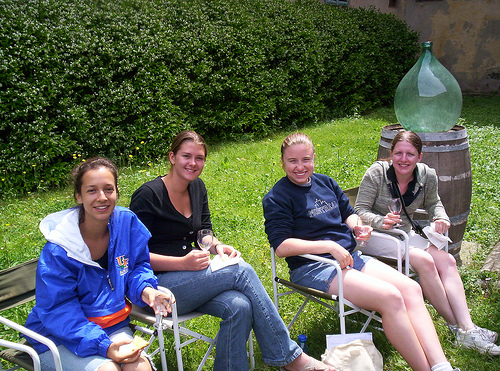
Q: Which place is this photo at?
A: It is at the yard.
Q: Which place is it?
A: It is a yard.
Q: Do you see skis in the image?
A: No, there are no skis.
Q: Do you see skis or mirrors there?
A: No, there are no skis or mirrors.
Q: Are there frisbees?
A: No, there are no frisbees.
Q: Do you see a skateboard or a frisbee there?
A: No, there are no frisbees or skateboards.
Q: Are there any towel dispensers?
A: No, there are no towel dispensers.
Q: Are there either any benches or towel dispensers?
A: No, there are no towel dispensers or benches.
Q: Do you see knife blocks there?
A: No, there are no knife blocks.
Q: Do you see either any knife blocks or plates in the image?
A: No, there are no knife blocks or plates.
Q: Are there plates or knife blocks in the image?
A: No, there are no knife blocks or plates.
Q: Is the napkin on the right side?
A: Yes, the napkin is on the right of the image.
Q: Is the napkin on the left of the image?
A: No, the napkin is on the right of the image.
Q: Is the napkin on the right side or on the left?
A: The napkin is on the right of the image.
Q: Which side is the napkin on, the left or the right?
A: The napkin is on the right of the image.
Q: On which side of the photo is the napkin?
A: The napkin is on the right of the image.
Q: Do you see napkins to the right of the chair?
A: Yes, there is a napkin to the right of the chair.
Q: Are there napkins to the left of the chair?
A: No, the napkin is to the right of the chair.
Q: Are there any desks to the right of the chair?
A: No, there is a napkin to the right of the chair.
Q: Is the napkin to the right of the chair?
A: Yes, the napkin is to the right of the chair.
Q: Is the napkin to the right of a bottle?
A: No, the napkin is to the right of the chair.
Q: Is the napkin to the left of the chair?
A: No, the napkin is to the right of the chair.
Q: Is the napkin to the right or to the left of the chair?
A: The napkin is to the right of the chair.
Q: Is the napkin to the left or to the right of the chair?
A: The napkin is to the right of the chair.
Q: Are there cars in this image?
A: No, there are no cars.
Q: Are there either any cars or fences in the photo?
A: No, there are no cars or fences.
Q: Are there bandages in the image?
A: No, there are no bandages.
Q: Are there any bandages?
A: No, there are no bandages.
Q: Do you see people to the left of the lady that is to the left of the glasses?
A: Yes, there is a person to the left of the lady.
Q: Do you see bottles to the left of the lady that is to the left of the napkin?
A: No, there is a person to the left of the lady.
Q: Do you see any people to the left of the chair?
A: Yes, there is a person to the left of the chair.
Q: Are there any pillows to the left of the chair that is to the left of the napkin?
A: No, there is a person to the left of the chair.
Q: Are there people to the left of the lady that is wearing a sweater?
A: Yes, there is a person to the left of the lady.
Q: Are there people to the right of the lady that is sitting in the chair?
A: No, the person is to the left of the lady.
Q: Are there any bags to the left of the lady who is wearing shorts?
A: No, there is a person to the left of the lady.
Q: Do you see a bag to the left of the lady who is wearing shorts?
A: No, there is a person to the left of the lady.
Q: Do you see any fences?
A: No, there are no fences.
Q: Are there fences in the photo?
A: No, there are no fences.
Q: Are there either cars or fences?
A: No, there are no fences or cars.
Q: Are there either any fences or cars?
A: No, there are no fences or cars.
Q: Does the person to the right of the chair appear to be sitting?
A: Yes, the person is sitting.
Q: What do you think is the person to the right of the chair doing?
A: The person is sitting.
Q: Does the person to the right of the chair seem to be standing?
A: No, the person is sitting.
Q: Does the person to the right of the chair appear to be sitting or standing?
A: The person is sitting.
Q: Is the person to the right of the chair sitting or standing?
A: The person is sitting.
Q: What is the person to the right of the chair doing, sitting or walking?
A: The person is sitting.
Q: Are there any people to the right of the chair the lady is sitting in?
A: Yes, there is a person to the right of the chair.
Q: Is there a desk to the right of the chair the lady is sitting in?
A: No, there is a person to the right of the chair.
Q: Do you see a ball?
A: No, there are no balls.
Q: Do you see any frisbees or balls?
A: No, there are no balls or frisbees.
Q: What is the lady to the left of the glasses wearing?
A: The lady is wearing a shirt.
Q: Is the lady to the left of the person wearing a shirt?
A: Yes, the lady is wearing a shirt.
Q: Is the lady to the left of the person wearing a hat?
A: No, the lady is wearing a shirt.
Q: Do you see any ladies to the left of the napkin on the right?
A: Yes, there is a lady to the left of the napkin.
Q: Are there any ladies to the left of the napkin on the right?
A: Yes, there is a lady to the left of the napkin.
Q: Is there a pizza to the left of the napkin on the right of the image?
A: No, there is a lady to the left of the napkin.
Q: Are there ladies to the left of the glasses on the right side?
A: Yes, there is a lady to the left of the glasses.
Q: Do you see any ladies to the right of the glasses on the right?
A: No, the lady is to the left of the glasses.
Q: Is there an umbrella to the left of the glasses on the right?
A: No, there is a lady to the left of the glasses.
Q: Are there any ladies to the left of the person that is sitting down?
A: Yes, there is a lady to the left of the person.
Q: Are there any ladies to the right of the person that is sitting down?
A: No, the lady is to the left of the person.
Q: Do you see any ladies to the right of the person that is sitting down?
A: No, the lady is to the left of the person.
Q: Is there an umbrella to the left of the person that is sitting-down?
A: No, there is a lady to the left of the person.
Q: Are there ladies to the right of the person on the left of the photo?
A: Yes, there is a lady to the right of the person.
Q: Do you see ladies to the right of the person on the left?
A: Yes, there is a lady to the right of the person.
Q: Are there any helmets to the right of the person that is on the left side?
A: No, there is a lady to the right of the person.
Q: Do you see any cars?
A: No, there are no cars.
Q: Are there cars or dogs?
A: No, there are no cars or dogs.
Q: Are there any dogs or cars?
A: No, there are no cars or dogs.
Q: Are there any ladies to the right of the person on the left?
A: Yes, there is a lady to the right of the person.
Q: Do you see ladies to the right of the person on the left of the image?
A: Yes, there is a lady to the right of the person.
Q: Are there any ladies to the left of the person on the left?
A: No, the lady is to the right of the person.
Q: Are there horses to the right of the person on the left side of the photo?
A: No, there is a lady to the right of the person.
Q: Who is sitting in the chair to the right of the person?
A: The lady is sitting in the chair.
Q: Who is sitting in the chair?
A: The lady is sitting in the chair.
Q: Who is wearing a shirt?
A: The lady is wearing a shirt.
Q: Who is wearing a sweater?
A: The lady is wearing a sweater.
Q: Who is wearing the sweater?
A: The lady is wearing a sweater.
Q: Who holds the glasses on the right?
A: The lady holds the glasses.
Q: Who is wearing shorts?
A: The lady is wearing shorts.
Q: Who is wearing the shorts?
A: The lady is wearing shorts.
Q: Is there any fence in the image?
A: No, there are no fences.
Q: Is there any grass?
A: Yes, there is grass.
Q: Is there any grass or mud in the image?
A: Yes, there is grass.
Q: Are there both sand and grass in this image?
A: No, there is grass but no sand.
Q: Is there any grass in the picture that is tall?
A: Yes, there is tall grass.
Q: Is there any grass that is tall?
A: Yes, there is grass that is tall.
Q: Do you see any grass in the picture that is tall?
A: Yes, there is grass that is tall.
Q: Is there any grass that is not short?
A: Yes, there is tall grass.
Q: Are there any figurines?
A: No, there are no figurines.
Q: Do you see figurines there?
A: No, there are no figurines.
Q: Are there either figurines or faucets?
A: No, there are no figurines or faucets.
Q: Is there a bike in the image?
A: No, there are no bikes.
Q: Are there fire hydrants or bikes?
A: No, there are no bikes or fire hydrants.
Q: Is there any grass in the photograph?
A: Yes, there is grass.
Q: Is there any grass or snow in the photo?
A: Yes, there is grass.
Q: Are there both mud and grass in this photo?
A: No, there is grass but no mud.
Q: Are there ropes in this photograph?
A: No, there are no ropes.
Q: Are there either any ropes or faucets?
A: No, there are no ropes or faucets.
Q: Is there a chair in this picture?
A: Yes, there is a chair.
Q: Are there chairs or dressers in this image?
A: Yes, there is a chair.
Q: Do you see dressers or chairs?
A: Yes, there is a chair.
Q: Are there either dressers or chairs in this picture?
A: Yes, there is a chair.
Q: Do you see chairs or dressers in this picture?
A: Yes, there is a chair.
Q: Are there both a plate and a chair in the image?
A: No, there is a chair but no plates.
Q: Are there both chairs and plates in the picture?
A: No, there is a chair but no plates.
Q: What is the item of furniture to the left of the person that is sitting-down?
A: The piece of furniture is a chair.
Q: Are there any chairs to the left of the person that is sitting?
A: Yes, there is a chair to the left of the person.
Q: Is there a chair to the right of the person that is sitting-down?
A: No, the chair is to the left of the person.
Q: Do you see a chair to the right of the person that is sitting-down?
A: No, the chair is to the left of the person.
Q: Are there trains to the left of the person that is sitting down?
A: No, there is a chair to the left of the person.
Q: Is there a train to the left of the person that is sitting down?
A: No, there is a chair to the left of the person.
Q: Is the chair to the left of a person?
A: Yes, the chair is to the left of a person.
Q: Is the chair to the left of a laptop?
A: No, the chair is to the left of a person.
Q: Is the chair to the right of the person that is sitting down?
A: No, the chair is to the left of the person.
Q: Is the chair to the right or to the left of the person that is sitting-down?
A: The chair is to the left of the person.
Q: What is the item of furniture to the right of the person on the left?
A: The piece of furniture is a chair.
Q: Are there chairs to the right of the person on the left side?
A: Yes, there is a chair to the right of the person.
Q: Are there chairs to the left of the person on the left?
A: No, the chair is to the right of the person.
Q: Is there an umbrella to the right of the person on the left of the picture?
A: No, there is a chair to the right of the person.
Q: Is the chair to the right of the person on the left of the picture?
A: Yes, the chair is to the right of the person.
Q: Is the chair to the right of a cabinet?
A: No, the chair is to the right of the person.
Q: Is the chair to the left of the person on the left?
A: No, the chair is to the right of the person.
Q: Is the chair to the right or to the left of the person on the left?
A: The chair is to the right of the person.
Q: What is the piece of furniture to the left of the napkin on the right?
A: The piece of furniture is a chair.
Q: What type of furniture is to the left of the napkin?
A: The piece of furniture is a chair.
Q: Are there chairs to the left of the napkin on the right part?
A: Yes, there is a chair to the left of the napkin.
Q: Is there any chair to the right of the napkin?
A: No, the chair is to the left of the napkin.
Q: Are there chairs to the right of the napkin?
A: No, the chair is to the left of the napkin.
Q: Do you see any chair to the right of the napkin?
A: No, the chair is to the left of the napkin.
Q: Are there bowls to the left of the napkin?
A: No, there is a chair to the left of the napkin.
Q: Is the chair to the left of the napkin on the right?
A: Yes, the chair is to the left of the napkin.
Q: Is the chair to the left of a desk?
A: No, the chair is to the left of the napkin.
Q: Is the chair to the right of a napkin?
A: No, the chair is to the left of a napkin.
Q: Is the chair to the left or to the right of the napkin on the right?
A: The chair is to the left of the napkin.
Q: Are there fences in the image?
A: No, there are no fences.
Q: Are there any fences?
A: No, there are no fences.